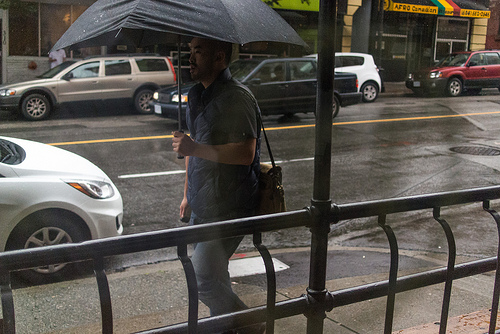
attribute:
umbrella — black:
[44, 1, 312, 53]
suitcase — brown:
[248, 92, 287, 220]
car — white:
[1, 132, 126, 280]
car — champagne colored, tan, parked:
[2, 51, 178, 121]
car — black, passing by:
[152, 58, 361, 122]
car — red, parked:
[404, 48, 499, 94]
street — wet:
[0, 90, 498, 332]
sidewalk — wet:
[3, 243, 495, 331]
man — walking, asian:
[169, 34, 261, 333]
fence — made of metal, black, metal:
[3, 184, 499, 333]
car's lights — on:
[150, 90, 188, 106]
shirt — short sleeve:
[183, 70, 263, 232]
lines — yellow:
[40, 106, 499, 178]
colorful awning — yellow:
[380, 1, 493, 21]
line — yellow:
[28, 102, 498, 149]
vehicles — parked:
[1, 49, 498, 124]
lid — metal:
[228, 252, 290, 278]